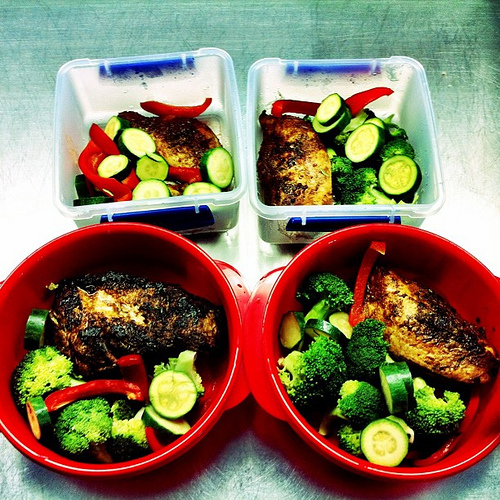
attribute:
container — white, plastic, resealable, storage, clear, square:
[43, 42, 249, 247]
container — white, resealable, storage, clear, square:
[242, 48, 453, 248]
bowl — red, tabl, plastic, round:
[2, 216, 259, 484]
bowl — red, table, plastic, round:
[240, 215, 500, 499]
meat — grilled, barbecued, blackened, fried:
[353, 257, 498, 391]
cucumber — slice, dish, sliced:
[374, 355, 420, 412]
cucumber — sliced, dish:
[358, 410, 420, 472]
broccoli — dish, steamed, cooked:
[342, 318, 390, 374]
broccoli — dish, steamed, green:
[278, 331, 349, 415]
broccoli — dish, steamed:
[329, 375, 386, 431]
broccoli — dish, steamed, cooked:
[283, 269, 356, 333]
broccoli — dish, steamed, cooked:
[406, 371, 468, 445]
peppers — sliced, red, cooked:
[43, 347, 156, 412]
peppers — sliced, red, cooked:
[140, 422, 169, 455]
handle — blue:
[283, 57, 385, 78]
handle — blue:
[96, 51, 193, 78]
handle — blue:
[287, 211, 403, 239]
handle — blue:
[93, 200, 220, 243]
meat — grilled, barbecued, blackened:
[41, 261, 230, 385]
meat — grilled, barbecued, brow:
[255, 99, 337, 209]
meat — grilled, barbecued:
[111, 107, 231, 181]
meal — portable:
[69, 87, 240, 212]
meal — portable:
[253, 76, 427, 212]